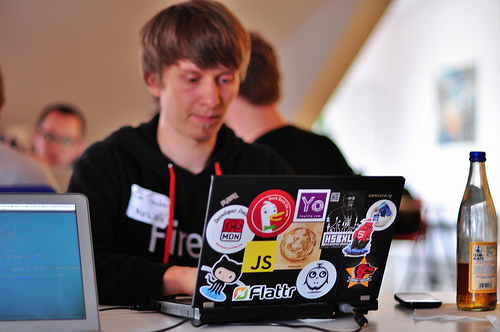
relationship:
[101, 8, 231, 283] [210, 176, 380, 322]
man on laptop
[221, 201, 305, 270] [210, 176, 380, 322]
stickers are on laptop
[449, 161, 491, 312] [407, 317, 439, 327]
bottle on table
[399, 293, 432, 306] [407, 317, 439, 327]
phone on table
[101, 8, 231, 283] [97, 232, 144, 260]
man wearing hoodie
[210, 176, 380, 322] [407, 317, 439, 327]
laptop on table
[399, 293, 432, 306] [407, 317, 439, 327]
phone on top of table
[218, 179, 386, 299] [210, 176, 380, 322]
screen of laptop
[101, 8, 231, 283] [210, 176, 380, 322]
man using laptop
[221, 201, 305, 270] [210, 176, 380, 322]
stickers are on back of laptop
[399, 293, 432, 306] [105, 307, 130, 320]
phone on desk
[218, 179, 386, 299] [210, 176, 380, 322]
screen on laptop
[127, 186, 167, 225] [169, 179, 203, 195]
tag on shirt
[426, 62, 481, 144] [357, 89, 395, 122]
picture on wall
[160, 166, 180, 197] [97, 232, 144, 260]
strings attached to hoodie